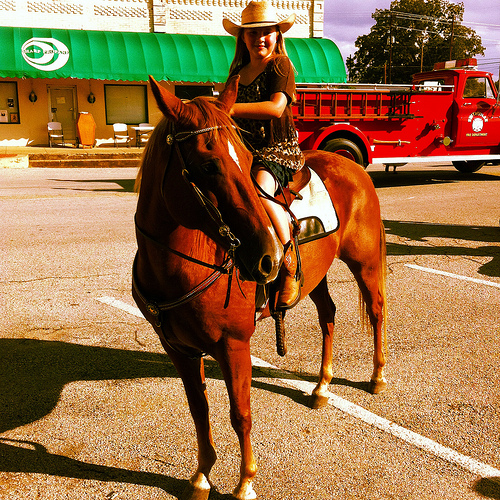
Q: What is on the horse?
A: Young girl.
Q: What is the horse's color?
A: Brown.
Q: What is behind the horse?
A: Fire truck.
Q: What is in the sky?
A: Clouds.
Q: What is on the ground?
A: Horse shadow.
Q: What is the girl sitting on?
A: A horse.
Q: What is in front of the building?
A: Fire truck.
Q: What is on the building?
A: Roof.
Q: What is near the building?
A: Tree.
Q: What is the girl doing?
A: Riding a horse.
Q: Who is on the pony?
A: The girl.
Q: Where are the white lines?
A: On asphalt.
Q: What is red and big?
A: Fire truck.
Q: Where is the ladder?
A: Side of truck.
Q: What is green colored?
A: Awning.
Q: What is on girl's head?
A: Cowboy hat.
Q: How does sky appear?
A: Cloudy.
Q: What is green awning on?
A: Building.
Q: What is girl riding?
A: Horse.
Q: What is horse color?
A: Brown.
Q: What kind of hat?
A: Cowboy.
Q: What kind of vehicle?
A: Truck.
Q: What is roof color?
A: Green.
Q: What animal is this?
A: A horse.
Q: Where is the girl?
A: On the horse.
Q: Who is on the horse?
A: A girl.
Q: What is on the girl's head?
A: A cowboy hat.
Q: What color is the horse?
A: Brown.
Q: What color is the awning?
A: Green.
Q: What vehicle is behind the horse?
A: A fire truck.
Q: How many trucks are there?
A: One.